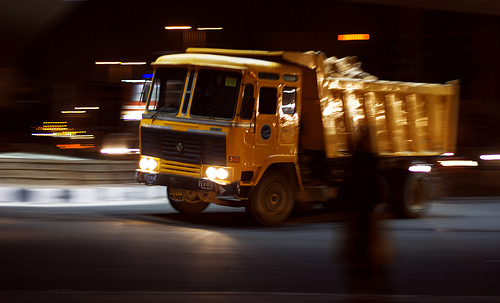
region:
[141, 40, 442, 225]
yellow construction truck in motion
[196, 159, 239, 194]
left headlight on front of truck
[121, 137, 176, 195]
right headlight on front of truck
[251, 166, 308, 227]
black left on front of truck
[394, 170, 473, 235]
black rear tire on left of truck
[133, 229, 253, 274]
reflection of light on pavement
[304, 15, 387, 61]
orange light over truck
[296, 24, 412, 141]
truck filled with debris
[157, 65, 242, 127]
windshield on front of truck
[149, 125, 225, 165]
black grill on front of truck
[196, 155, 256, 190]
Two lights on a dump truck.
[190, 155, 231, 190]
Two small light on a dump truck.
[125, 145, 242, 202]
Four lights on a bus.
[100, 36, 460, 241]
A dump truck on the street.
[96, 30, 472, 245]
A large dump truck on the street.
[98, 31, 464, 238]
A yellow dump truck on the street.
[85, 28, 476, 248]
A large yellow dump truck on the street.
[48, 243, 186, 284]
Part of a street.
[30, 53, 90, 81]
Part of a sky.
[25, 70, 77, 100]
Part of a black sky.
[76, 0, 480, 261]
dump truck driving on road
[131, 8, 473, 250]
dump truck is yellow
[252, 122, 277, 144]
dump truck has blue decal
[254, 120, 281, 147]
blue decal is located on door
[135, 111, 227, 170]
dump truck has black grill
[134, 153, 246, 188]
truck has four lights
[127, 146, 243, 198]
truck lights are lit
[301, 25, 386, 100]
dump truck carrying cargo in back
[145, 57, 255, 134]
truck has two windows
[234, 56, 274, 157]
truck has yellow arm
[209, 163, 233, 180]
light on the truck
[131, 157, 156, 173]
light on the truck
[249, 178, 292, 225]
tire on the truck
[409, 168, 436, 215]
tire on the truck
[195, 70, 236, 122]
window on the truck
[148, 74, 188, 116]
window on the truck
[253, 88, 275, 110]
window on the truck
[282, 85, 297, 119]
window on the truck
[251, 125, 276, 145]
circle on the truck